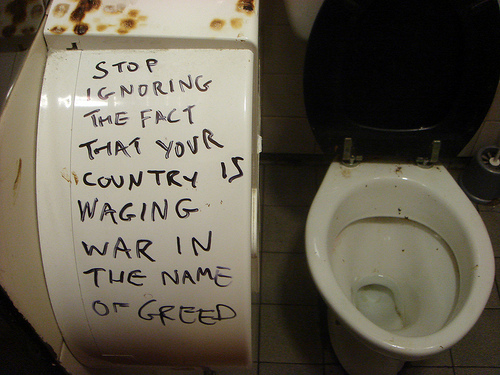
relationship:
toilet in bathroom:
[302, 4, 496, 373] [1, 0, 498, 371]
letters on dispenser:
[80, 57, 243, 328] [40, 3, 253, 368]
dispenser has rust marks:
[40, 3, 253, 368] [46, 2, 253, 39]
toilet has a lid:
[302, 4, 496, 373] [302, 2, 498, 169]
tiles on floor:
[262, 150, 497, 373] [260, 160, 497, 372]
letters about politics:
[80, 57, 243, 328] [76, 58, 243, 330]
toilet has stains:
[302, 4, 496, 373] [341, 165, 442, 262]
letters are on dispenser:
[80, 57, 243, 328] [40, 3, 253, 368]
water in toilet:
[353, 277, 407, 326] [302, 4, 496, 373]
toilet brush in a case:
[455, 145, 496, 207] [460, 146, 498, 206]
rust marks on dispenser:
[46, 2, 253, 39] [40, 3, 253, 368]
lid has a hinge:
[302, 2, 498, 169] [340, 137, 440, 166]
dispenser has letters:
[40, 3, 253, 368] [80, 57, 243, 328]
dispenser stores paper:
[40, 3, 253, 368] [250, 254, 262, 296]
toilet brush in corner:
[455, 145, 496, 207] [457, 131, 499, 203]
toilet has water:
[302, 4, 496, 373] [353, 277, 407, 326]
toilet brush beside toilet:
[455, 145, 496, 207] [302, 4, 496, 373]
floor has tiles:
[260, 160, 497, 372] [262, 150, 497, 373]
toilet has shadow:
[302, 4, 496, 373] [262, 0, 336, 369]